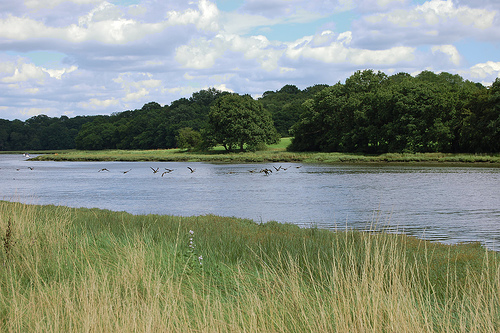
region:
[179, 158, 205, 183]
bird in flight over water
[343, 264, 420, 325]
tall brown weedlike grass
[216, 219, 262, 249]
green grass by water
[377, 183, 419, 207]
blue patch of water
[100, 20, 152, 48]
white fluffy clouds in sky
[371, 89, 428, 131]
tall green leafy trees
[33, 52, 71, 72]
light blue patch of sky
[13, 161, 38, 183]
two birds flying over water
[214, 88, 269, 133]
bushy green leafy tree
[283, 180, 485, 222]
calm blue water in center of photo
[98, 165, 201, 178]
some birds flying over a body of water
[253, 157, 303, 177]
birds landing on a lake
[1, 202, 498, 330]
tall grass along the edge of a lake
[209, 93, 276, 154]
a few trees near the edge of the lake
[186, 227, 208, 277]
flowers growing in the tall grass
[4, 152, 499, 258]
a large body of water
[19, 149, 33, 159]
two white buoys in the water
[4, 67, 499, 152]
a line of trees behind the lake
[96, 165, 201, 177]
birds flying close to the water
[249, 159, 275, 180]
birds sitting in the water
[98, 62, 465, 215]
Green trees are by the water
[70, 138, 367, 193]
Birds are flying low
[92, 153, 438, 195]
Birds are flying over the water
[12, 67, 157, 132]
The sky is blue and cloudy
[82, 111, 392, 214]
The trees are on the grass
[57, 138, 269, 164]
The grass is on the other side of the water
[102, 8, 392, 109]
The sun is behind the clouds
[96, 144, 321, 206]
birds are on the water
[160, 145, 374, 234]
the water is calm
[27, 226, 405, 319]
the grass is high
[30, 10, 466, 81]
the clouds are fluffy and white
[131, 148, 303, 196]
the birds are looking for fish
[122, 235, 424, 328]
the grass is golden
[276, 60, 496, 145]
the trees are fluffy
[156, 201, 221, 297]
flowers in the grass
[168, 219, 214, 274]
the flowers are white and small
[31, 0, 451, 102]
the sky is partly cloudy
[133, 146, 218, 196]
The birds are flying low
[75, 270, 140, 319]
Some of the weeds are brown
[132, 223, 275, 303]
The grass is very tall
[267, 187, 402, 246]
The water is calm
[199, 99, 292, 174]
The tree leaves are green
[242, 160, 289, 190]
The birds are diving into the water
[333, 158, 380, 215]
The water is dark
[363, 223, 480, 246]
The water has a few ripples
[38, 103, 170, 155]
Trees are in the distance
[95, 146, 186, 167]
The grass has been mowed